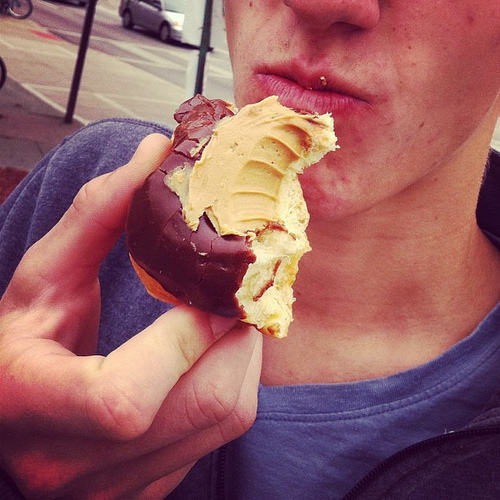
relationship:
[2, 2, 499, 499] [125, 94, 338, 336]
teen has donut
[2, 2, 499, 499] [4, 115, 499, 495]
teen wears shirt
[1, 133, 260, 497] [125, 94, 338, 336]
hand holds donut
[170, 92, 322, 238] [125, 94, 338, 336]
peanut butter on donut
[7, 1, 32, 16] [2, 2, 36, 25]
tire on bike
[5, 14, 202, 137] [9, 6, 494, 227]
sidewalk in city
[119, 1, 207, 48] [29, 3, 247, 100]
sedan on street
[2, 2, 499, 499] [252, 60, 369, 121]
teen has lips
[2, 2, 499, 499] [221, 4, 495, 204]
teen has face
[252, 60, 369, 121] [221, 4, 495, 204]
lips on face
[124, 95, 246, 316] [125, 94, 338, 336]
chocolate on donut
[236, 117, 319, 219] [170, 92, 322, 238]
bites in peanut butter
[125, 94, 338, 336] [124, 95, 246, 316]
donut has chocolate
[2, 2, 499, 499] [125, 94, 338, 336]
teen holds donut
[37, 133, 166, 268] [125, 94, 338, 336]
thumb on donut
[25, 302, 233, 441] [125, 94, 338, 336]
finger holds donut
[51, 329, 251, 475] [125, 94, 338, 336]
finger holds donut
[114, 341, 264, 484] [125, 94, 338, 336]
finger holds donut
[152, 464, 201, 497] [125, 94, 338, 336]
finger holds donut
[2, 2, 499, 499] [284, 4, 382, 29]
teen has nose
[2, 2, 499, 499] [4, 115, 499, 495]
teen wearing shirt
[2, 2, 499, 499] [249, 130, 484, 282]
teen has neck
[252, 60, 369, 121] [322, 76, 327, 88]
lips have spots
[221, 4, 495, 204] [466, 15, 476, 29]
face has pimple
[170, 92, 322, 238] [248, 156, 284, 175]
peanut butter has lines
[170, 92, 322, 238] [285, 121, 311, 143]
peanut butter has line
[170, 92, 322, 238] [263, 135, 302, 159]
peanut butter has line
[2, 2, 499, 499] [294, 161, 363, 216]
teen has chin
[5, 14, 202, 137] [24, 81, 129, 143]
sidewalk has lines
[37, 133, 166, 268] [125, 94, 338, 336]
thumb holds donut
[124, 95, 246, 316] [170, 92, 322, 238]
chocolate with peanut butter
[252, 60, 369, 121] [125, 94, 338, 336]
lips near donut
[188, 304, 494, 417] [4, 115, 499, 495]
seam on shirt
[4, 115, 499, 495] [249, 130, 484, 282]
shirt near neck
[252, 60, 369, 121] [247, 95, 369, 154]
mouth has blemishes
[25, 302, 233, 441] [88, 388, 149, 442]
finger has wrinkles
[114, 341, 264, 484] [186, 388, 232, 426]
finger has wrinkles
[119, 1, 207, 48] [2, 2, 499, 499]
sedan behind teen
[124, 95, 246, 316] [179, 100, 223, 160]
chocolate has cracks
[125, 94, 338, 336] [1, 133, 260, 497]
donut in hand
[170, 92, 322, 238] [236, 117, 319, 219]
peanut butter has bites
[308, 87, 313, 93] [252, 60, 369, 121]
crumb on lips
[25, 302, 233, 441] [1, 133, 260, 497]
finger on hand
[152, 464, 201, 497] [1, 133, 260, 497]
finger on hand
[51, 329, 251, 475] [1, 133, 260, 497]
finger on hand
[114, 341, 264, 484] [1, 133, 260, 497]
finger on hand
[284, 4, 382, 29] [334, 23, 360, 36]
nose has nostril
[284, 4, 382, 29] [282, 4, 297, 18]
nose has nostril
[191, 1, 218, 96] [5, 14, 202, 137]
pole on sidewalk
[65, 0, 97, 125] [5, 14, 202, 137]
pole on sidewalk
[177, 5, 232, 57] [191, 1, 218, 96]
signs on pole